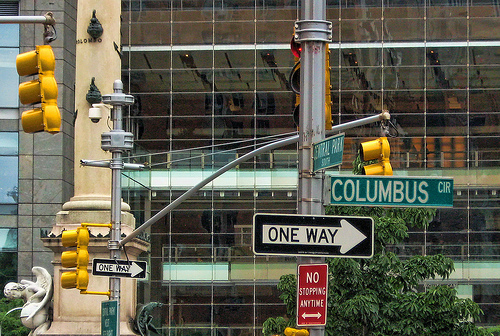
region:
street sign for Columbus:
[320, 160, 474, 232]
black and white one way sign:
[247, 202, 380, 269]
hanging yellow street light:
[9, 38, 74, 143]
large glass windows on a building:
[127, 11, 275, 159]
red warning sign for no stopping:
[280, 257, 337, 332]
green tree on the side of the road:
[265, 192, 488, 334]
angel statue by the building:
[5, 258, 60, 334]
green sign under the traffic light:
[87, 295, 132, 334]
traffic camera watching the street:
[81, 94, 108, 127]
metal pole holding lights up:
[95, 72, 142, 334]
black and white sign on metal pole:
[250, 212, 375, 259]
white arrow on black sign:
[261, 223, 368, 253]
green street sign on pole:
[324, 177, 455, 212]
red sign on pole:
[293, 260, 333, 324]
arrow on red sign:
[301, 309, 323, 319]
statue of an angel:
[3, 265, 50, 327]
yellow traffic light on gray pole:
[58, 218, 110, 298]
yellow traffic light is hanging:
[359, 137, 395, 174]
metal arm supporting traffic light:
[120, 135, 295, 250]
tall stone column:
[40, 0, 149, 335]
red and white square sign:
[279, 253, 356, 330]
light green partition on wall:
[156, 254, 246, 281]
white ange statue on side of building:
[6, 273, 79, 321]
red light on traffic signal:
[267, 22, 337, 61]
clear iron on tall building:
[175, 33, 250, 130]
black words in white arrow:
[259, 224, 356, 248]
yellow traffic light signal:
[21, 41, 86, 162]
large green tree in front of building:
[345, 261, 465, 312]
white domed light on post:
[76, 97, 115, 127]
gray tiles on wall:
[14, 158, 54, 193]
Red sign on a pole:
[296, 261, 326, 324]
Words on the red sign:
[300, 270, 322, 305]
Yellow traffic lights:
[12, 45, 387, 295]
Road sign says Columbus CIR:
[326, 175, 456, 207]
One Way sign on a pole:
[251, 212, 374, 257]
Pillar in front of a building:
[50, 2, 141, 334]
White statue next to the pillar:
[1, 265, 51, 335]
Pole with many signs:
[298, 1, 327, 334]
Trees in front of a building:
[262, 149, 494, 334]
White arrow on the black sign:
[262, 219, 365, 253]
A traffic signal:
[6, 44, 70, 139]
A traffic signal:
[55, 222, 98, 298]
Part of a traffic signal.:
[353, 131, 406, 182]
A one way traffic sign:
[91, 253, 154, 283]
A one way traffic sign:
[252, 212, 386, 263]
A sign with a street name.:
[319, 169, 464, 214]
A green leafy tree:
[259, 177, 488, 334]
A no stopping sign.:
[292, 259, 340, 325]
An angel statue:
[2, 262, 65, 334]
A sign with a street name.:
[311, 130, 355, 179]